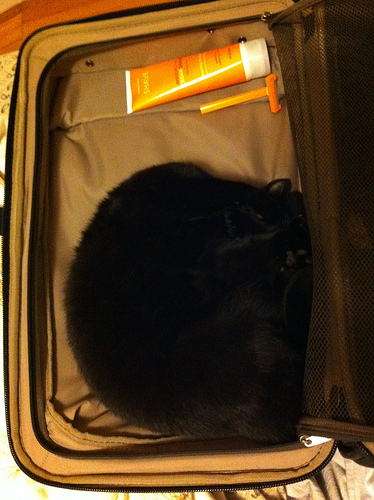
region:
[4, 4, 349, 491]
brown suitcase with black trim and zipper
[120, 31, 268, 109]
orange tube with white cap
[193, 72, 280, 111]
plastic orange shaver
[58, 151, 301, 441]
black cat curled up and sleeping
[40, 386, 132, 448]
black stitching around corner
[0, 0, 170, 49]
brown floor boards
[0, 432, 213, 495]
printed gold and white fabric under suitcase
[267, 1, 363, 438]
black mesh covering side of suitcase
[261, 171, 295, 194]
pointed tip of cat ear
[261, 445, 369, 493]
rumpled light brown fabric under case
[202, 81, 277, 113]
an orange razor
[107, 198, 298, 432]
big furry black thing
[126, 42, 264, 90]
a beauty product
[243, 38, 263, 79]
white cap of a beauty product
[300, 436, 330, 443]
zipper on a luggage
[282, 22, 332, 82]
mesh fabric on a lugagge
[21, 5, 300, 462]
luggage containing items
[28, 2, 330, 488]
luggage with three items inside it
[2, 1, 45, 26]
brown hardwood flooring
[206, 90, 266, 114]
handle of the razor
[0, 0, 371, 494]
inside of open suitcase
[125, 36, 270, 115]
tube with white cap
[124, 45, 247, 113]
orange body of tube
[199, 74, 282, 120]
plactic disposable razor blade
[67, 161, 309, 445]
curled up black cat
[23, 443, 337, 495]
zipper on side of suitcase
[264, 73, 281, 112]
orange cover on razor blade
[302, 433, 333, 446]
metal tab on zipper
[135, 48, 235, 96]
words on plastic bottle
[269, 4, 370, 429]
netting inside suitcase cover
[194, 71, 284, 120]
th razor is in the suitcase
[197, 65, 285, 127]
the razor is yellow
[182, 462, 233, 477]
the suitcae is brown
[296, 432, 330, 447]
the zipper is silver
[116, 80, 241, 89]
the tube is shiney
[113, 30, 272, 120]
the tube is orange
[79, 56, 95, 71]
the button is black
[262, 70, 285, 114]
the cap is on the razor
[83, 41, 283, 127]
the razor is next to the tube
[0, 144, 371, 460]
A black cat in a suitcase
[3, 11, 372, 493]
A suitcase containing a sleeping black cat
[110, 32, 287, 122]
Shaving cream and a razor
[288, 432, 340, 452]
A silver suitcase zipper pull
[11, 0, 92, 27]
A wooden floor surface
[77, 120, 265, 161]
A brown suitcase lining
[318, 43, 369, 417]
Brown mesh inside a suitcase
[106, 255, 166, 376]
Black cat fur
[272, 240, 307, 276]
A black cat's paw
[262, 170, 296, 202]
A black cat's ear